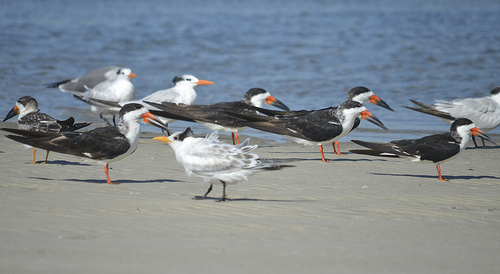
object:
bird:
[151, 128, 294, 203]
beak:
[151, 136, 172, 143]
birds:
[349, 117, 498, 185]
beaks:
[265, 95, 289, 112]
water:
[0, 1, 500, 65]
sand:
[0, 205, 500, 266]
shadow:
[206, 196, 321, 203]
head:
[151, 127, 195, 148]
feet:
[315, 158, 331, 163]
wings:
[285, 117, 341, 142]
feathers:
[177, 126, 194, 140]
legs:
[214, 179, 230, 203]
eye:
[173, 136, 178, 139]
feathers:
[140, 100, 199, 121]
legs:
[315, 143, 331, 163]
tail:
[140, 99, 198, 124]